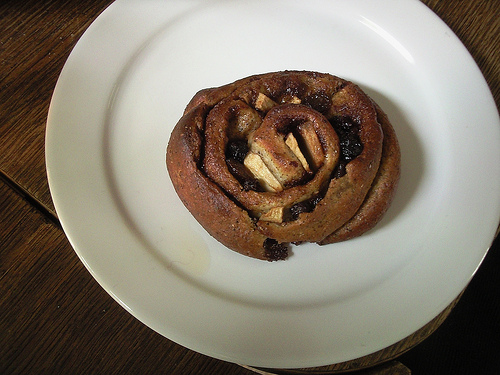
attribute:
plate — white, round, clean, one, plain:
[39, 2, 483, 362]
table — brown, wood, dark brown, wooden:
[1, 3, 481, 372]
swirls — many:
[194, 87, 358, 213]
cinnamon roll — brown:
[164, 67, 408, 267]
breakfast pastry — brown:
[161, 66, 403, 264]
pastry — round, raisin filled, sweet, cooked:
[163, 67, 403, 263]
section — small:
[0, 179, 260, 373]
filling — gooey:
[330, 112, 363, 180]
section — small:
[156, 1, 389, 83]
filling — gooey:
[241, 143, 282, 193]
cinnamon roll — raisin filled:
[167, 70, 399, 259]